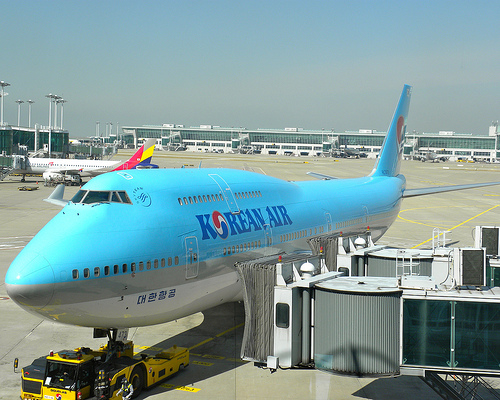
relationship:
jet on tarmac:
[0, 143, 161, 180] [2, 149, 494, 398]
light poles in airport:
[0, 74, 84, 135] [2, 69, 497, 359]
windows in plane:
[71, 186, 136, 206] [3, 83, 500, 330]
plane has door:
[3, 83, 500, 330] [185, 233, 202, 281]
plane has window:
[14, 139, 389, 339] [77, 180, 108, 205]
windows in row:
[69, 251, 183, 279] [65, 249, 186, 288]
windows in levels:
[69, 251, 183, 279] [177, 193, 224, 206]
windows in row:
[69, 251, 183, 279] [220, 225, 341, 267]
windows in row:
[69, 251, 183, 279] [65, 181, 135, 205]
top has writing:
[7, 158, 405, 235] [196, 204, 293, 239]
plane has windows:
[3, 83, 500, 330] [69, 186, 132, 210]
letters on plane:
[189, 202, 303, 232] [7, 77, 447, 344]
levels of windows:
[176, 192, 322, 244] [167, 183, 262, 209]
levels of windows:
[176, 192, 322, 244] [71, 211, 383, 283]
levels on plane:
[176, 192, 322, 244] [3, 83, 500, 330]